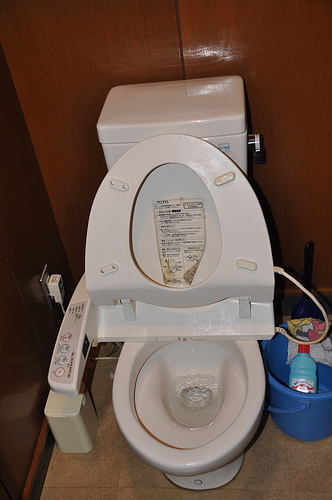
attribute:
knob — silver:
[250, 128, 268, 158]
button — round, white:
[192, 478, 204, 486]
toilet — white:
[75, 75, 279, 483]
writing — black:
[154, 198, 173, 206]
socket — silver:
[46, 268, 67, 302]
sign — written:
[149, 200, 216, 278]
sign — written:
[153, 198, 206, 288]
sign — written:
[53, 341, 77, 356]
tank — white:
[103, 89, 253, 145]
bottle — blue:
[287, 341, 318, 393]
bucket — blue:
[260, 315, 330, 444]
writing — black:
[65, 298, 84, 317]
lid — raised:
[81, 129, 280, 340]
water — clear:
[148, 345, 231, 426]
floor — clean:
[240, 442, 327, 497]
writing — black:
[152, 200, 204, 233]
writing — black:
[183, 201, 204, 208]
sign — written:
[46, 298, 86, 385]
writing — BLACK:
[67, 299, 85, 318]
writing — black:
[158, 195, 202, 276]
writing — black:
[150, 198, 205, 281]